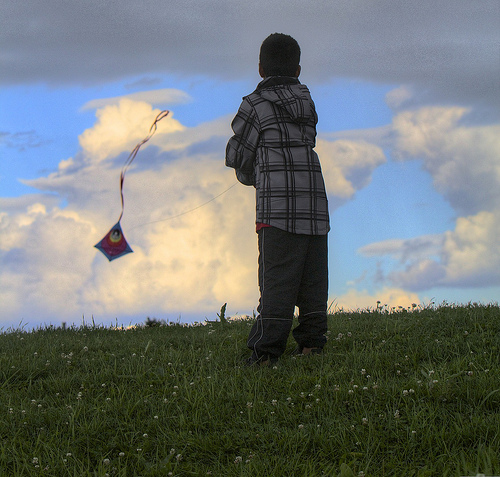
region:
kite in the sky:
[82, 204, 149, 259]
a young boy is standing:
[214, 28, 328, 357]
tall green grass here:
[250, 410, 349, 450]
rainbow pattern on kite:
[97, 226, 141, 263]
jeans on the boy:
[262, 253, 335, 313]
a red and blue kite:
[95, 104, 172, 263]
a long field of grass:
[2, 325, 499, 474]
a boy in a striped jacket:
[217, 29, 334, 347]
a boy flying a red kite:
[88, 24, 343, 356]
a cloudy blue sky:
[5, 105, 222, 315]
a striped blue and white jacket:
[223, 78, 338, 232]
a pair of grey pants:
[246, 224, 333, 352]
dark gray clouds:
[6, 0, 218, 81]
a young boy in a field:
[208, 30, 340, 356]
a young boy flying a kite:
[92, 39, 335, 365]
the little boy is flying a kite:
[85, 5, 355, 426]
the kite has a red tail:
[103, 88, 183, 203]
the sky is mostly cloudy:
[35, 64, 448, 290]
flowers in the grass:
[195, 365, 413, 447]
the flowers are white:
[271, 354, 450, 449]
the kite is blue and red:
[61, 208, 151, 275]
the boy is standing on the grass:
[214, 22, 374, 374]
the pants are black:
[222, 216, 352, 355]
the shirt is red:
[243, 206, 286, 236]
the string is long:
[135, 179, 243, 243]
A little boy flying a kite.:
[93, 31, 331, 368]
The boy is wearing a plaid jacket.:
[225, 78, 326, 235]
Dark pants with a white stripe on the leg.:
[253, 215, 325, 360]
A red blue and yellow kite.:
[90, 220, 132, 262]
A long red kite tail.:
[113, 108, 173, 229]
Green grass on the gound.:
[0, 300, 496, 475]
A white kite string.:
[118, 180, 240, 230]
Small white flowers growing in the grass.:
[0, 300, 495, 475]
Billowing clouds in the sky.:
[1, 0, 499, 322]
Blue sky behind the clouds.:
[0, 0, 497, 325]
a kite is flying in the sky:
[78, 92, 178, 278]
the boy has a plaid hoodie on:
[223, 77, 336, 233]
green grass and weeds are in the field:
[2, 305, 492, 467]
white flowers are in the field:
[12, 334, 492, 460]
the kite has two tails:
[115, 95, 176, 221]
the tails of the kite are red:
[111, 103, 173, 223]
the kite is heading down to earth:
[53, 175, 213, 347]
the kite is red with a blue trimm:
[86, 216, 140, 265]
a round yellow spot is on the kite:
[103, 224, 124, 247]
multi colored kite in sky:
[82, 220, 157, 277]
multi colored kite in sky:
[79, 215, 146, 267]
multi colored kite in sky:
[91, 217, 144, 268]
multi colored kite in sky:
[87, 218, 146, 269]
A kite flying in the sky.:
[59, 133, 159, 285]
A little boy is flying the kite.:
[240, 28, 346, 350]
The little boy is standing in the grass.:
[213, 15, 350, 347]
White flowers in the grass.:
[133, 385, 432, 460]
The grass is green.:
[28, 323, 485, 473]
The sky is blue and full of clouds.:
[23, 13, 498, 173]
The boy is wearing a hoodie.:
[241, 88, 328, 240]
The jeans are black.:
[263, 231, 336, 360]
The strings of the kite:
[118, 107, 170, 220]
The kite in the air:
[93, 220, 135, 263]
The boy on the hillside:
[223, 30, 333, 366]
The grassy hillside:
[0, 298, 497, 474]